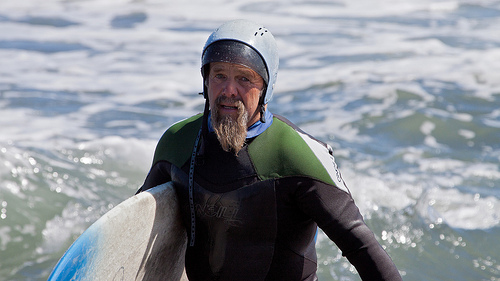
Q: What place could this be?
A: It is a sea.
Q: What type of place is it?
A: It is a sea.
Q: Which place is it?
A: It is a sea.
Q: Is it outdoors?
A: Yes, it is outdoors.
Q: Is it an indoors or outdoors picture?
A: It is outdoors.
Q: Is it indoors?
A: No, it is outdoors.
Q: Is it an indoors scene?
A: No, it is outdoors.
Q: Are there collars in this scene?
A: Yes, there is a collar.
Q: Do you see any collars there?
A: Yes, there is a collar.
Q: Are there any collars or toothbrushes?
A: Yes, there is a collar.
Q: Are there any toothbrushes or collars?
A: Yes, there is a collar.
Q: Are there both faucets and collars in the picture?
A: No, there is a collar but no faucets.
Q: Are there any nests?
A: No, there are no nests.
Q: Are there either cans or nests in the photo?
A: No, there are no nests or cans.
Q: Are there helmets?
A: Yes, there is a helmet.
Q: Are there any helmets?
A: Yes, there is a helmet.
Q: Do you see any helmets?
A: Yes, there is a helmet.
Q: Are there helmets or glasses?
A: Yes, there is a helmet.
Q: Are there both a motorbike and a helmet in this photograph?
A: No, there is a helmet but no motorcycles.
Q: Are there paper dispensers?
A: No, there are no paper dispensers.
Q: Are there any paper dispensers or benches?
A: No, there are no paper dispensers or benches.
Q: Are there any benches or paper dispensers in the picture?
A: No, there are no paper dispensers or benches.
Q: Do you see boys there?
A: No, there are no boys.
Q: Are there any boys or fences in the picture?
A: No, there are no boys or fences.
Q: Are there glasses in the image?
A: No, there are no glasses.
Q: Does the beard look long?
A: Yes, the beard is long.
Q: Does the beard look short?
A: No, the beard is long.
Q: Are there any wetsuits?
A: Yes, there is a wetsuit.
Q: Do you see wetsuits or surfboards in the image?
A: Yes, there is a wetsuit.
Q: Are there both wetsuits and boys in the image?
A: No, there is a wetsuit but no boys.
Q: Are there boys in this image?
A: No, there are no boys.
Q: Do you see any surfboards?
A: Yes, there is a surfboard.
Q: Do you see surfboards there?
A: Yes, there is a surfboard.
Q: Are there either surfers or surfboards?
A: Yes, there is a surfboard.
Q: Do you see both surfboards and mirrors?
A: No, there is a surfboard but no mirrors.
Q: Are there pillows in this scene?
A: No, there are no pillows.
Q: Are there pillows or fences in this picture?
A: No, there are no pillows or fences.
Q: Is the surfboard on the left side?
A: Yes, the surfboard is on the left of the image.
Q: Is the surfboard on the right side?
A: No, the surfboard is on the left of the image.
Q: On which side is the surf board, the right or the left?
A: The surf board is on the left of the image.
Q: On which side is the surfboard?
A: The surfboard is on the left of the image.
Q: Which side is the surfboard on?
A: The surfboard is on the left of the image.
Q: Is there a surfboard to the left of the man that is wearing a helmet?
A: Yes, there is a surfboard to the left of the man.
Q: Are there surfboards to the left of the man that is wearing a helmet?
A: Yes, there is a surfboard to the left of the man.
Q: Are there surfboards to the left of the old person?
A: Yes, there is a surfboard to the left of the man.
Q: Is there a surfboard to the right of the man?
A: No, the surfboard is to the left of the man.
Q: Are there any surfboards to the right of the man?
A: No, the surfboard is to the left of the man.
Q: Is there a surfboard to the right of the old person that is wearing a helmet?
A: No, the surfboard is to the left of the man.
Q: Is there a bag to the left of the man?
A: No, there is a surfboard to the left of the man.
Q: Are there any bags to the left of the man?
A: No, there is a surfboard to the left of the man.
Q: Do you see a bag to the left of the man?
A: No, there is a surfboard to the left of the man.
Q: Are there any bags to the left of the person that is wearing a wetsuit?
A: No, there is a surfboard to the left of the man.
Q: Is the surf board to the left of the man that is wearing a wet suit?
A: Yes, the surf board is to the left of the man.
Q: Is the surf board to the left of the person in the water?
A: Yes, the surf board is to the left of the man.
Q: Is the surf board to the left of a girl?
A: No, the surf board is to the left of the man.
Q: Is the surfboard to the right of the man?
A: No, the surfboard is to the left of the man.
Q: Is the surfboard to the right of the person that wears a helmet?
A: No, the surfboard is to the left of the man.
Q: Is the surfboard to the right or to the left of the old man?
A: The surfboard is to the left of the man.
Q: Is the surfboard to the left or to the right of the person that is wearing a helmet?
A: The surfboard is to the left of the man.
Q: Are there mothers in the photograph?
A: No, there are no mothers.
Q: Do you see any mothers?
A: No, there are no mothers.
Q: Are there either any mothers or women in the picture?
A: No, there are no mothers or women.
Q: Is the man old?
A: Yes, the man is old.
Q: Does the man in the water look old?
A: Yes, the man is old.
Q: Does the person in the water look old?
A: Yes, the man is old.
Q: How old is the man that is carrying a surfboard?
A: The man is old.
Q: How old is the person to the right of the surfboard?
A: The man is old.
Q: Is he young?
A: No, the man is old.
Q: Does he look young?
A: No, the man is old.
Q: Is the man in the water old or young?
A: The man is old.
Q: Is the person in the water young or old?
A: The man is old.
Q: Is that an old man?
A: Yes, that is an old man.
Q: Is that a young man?
A: No, that is an old man.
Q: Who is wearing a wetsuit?
A: The man is wearing a wetsuit.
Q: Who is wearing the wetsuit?
A: The man is wearing a wetsuit.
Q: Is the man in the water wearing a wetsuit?
A: Yes, the man is wearing a wetsuit.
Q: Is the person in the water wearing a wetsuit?
A: Yes, the man is wearing a wetsuit.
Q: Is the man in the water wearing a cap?
A: No, the man is wearing a wetsuit.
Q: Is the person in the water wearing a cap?
A: No, the man is wearing a wetsuit.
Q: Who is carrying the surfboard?
A: The man is carrying the surfboard.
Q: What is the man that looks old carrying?
A: The man is carrying a surf board.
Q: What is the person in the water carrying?
A: The man is carrying a surf board.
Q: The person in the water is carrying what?
A: The man is carrying a surf board.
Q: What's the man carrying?
A: The man is carrying a surf board.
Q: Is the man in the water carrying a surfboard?
A: Yes, the man is carrying a surfboard.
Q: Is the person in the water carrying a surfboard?
A: Yes, the man is carrying a surfboard.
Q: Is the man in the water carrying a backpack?
A: No, the man is carrying a surfboard.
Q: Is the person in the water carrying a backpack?
A: No, the man is carrying a surfboard.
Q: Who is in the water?
A: The man is in the water.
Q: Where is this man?
A: The man is in the water.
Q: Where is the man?
A: The man is in the water.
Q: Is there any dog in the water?
A: No, there is a man in the water.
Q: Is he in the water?
A: Yes, the man is in the water.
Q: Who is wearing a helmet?
A: The man is wearing a helmet.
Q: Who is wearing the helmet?
A: The man is wearing a helmet.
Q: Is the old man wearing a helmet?
A: Yes, the man is wearing a helmet.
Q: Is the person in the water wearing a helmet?
A: Yes, the man is wearing a helmet.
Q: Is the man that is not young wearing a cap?
A: No, the man is wearing a helmet.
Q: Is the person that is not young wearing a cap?
A: No, the man is wearing a helmet.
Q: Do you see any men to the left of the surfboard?
A: No, the man is to the right of the surfboard.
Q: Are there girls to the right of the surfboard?
A: No, there is a man to the right of the surfboard.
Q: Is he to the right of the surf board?
A: Yes, the man is to the right of the surf board.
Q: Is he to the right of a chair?
A: No, the man is to the right of the surf board.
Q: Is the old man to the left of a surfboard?
A: No, the man is to the right of a surfboard.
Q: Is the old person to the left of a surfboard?
A: No, the man is to the right of a surfboard.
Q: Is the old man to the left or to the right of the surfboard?
A: The man is to the right of the surfboard.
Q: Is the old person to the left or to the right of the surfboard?
A: The man is to the right of the surfboard.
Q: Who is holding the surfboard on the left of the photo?
A: The man is holding the surfboard.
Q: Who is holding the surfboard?
A: The man is holding the surfboard.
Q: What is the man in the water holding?
A: The man is holding the surfboard.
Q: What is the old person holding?
A: The man is holding the surfboard.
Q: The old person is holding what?
A: The man is holding the surfboard.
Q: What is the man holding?
A: The man is holding the surfboard.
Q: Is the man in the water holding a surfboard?
A: Yes, the man is holding a surfboard.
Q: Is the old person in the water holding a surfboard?
A: Yes, the man is holding a surfboard.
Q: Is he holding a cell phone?
A: No, the man is holding a surfboard.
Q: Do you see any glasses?
A: No, there are no glasses.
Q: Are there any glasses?
A: No, there are no glasses.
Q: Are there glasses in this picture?
A: No, there are no glasses.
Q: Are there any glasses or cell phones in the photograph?
A: No, there are no glasses or cell phones.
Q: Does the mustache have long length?
A: Yes, the mustache is long.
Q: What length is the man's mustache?
A: The moustache is long.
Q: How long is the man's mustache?
A: The moustache is long.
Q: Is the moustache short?
A: No, the moustache is long.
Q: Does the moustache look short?
A: No, the moustache is long.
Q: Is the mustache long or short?
A: The mustache is long.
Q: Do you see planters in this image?
A: No, there are no planters.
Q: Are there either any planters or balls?
A: No, there are no planters or balls.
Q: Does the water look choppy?
A: Yes, the water is choppy.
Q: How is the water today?
A: The water is choppy.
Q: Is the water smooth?
A: No, the water is choppy.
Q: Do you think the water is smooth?
A: No, the water is choppy.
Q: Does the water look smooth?
A: No, the water is choppy.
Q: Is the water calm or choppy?
A: The water is choppy.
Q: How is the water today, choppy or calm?
A: The water is choppy.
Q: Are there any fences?
A: No, there are no fences.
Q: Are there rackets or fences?
A: No, there are no fences or rackets.